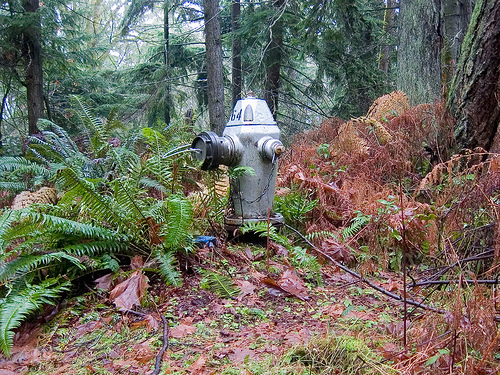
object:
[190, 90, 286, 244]
hydrant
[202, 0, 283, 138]
trunks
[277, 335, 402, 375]
vegetation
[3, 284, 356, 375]
floor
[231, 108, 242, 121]
numbers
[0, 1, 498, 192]
woods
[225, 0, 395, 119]
pine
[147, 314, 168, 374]
sticks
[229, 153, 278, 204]
chain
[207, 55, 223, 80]
bark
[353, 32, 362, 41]
pine needles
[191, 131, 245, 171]
cylinder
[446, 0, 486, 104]
moss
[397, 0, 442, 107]
trunk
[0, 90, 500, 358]
bushes